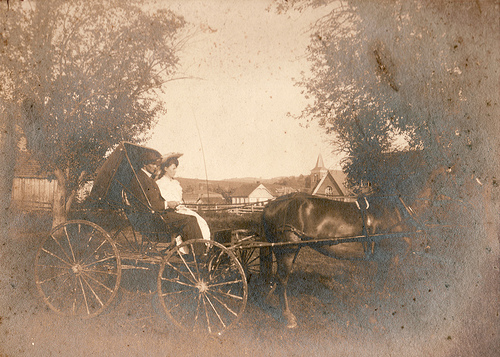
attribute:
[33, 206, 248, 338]
buggy — horse drawn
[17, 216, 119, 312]
wheel — faded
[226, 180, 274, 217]
building — white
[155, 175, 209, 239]
dress — white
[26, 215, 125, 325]
wheel — faded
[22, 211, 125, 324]
rear wheel — large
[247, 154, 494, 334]
horse — faded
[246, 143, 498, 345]
horse — black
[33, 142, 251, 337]
cart — faded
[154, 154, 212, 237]
woman — faded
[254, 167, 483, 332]
brown horse — faded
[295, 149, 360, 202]
building — faded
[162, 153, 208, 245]
woman's — faded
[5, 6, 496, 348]
photo — faded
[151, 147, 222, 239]
woman — faded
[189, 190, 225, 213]
barn — faded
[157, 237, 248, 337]
wheel — faded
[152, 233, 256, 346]
wheel — faded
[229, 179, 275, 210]
building — white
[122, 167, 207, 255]
suit — black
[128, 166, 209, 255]
suit — black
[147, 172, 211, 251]
dress — white